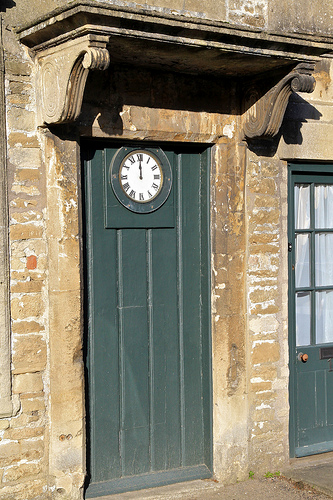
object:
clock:
[115, 147, 163, 203]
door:
[83, 140, 211, 495]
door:
[289, 167, 331, 461]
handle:
[299, 350, 310, 365]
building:
[0, 0, 332, 497]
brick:
[8, 224, 49, 243]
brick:
[13, 293, 44, 319]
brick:
[7, 130, 42, 150]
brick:
[253, 210, 283, 228]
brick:
[250, 232, 279, 245]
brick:
[248, 341, 281, 362]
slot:
[319, 350, 331, 360]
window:
[293, 182, 331, 348]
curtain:
[292, 184, 331, 346]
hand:
[138, 158, 143, 181]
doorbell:
[287, 243, 292, 253]